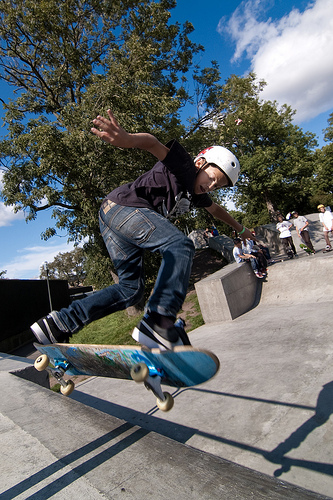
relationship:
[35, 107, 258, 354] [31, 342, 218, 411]
man doing tricks on skateboard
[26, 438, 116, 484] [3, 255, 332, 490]
shadow on ramp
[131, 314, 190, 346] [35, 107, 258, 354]
shoe on man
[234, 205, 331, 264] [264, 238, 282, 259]
skaters on ramp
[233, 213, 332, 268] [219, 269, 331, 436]
people sitting in concrete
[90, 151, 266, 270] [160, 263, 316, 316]
boy sitting on wall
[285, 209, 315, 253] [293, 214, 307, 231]
man wearing grey shirt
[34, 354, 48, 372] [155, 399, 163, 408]
tire has part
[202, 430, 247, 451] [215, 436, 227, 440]
shade has part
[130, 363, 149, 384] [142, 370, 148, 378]
tire has part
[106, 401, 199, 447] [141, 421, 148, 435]
shade has part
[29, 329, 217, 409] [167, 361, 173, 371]
board has part